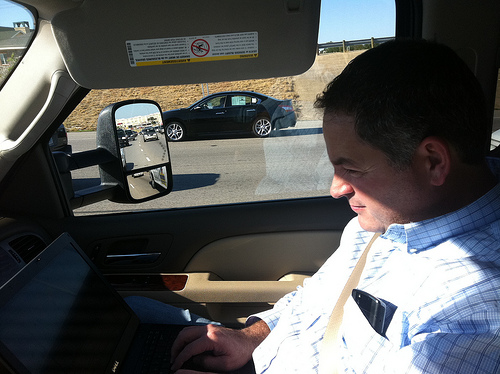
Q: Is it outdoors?
A: Yes, it is outdoors.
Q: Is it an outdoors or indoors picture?
A: It is outdoors.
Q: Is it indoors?
A: No, it is outdoors.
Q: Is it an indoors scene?
A: No, it is outdoors.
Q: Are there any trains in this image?
A: No, there are no trains.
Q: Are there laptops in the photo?
A: Yes, there is a laptop.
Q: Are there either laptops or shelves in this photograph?
A: Yes, there is a laptop.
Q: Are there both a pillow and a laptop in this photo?
A: No, there is a laptop but no pillows.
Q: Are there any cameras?
A: No, there are no cameras.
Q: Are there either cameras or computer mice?
A: No, there are no cameras or computer mice.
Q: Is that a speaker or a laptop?
A: That is a laptop.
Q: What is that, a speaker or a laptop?
A: That is a laptop.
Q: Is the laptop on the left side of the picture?
A: Yes, the laptop is on the left of the image.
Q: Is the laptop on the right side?
A: No, the laptop is on the left of the image.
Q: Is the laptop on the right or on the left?
A: The laptop is on the left of the image.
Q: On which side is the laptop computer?
A: The laptop computer is on the left of the image.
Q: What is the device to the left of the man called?
A: The device is a laptop.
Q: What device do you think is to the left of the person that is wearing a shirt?
A: The device is a laptop.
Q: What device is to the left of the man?
A: The device is a laptop.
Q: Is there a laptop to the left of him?
A: Yes, there is a laptop to the left of the man.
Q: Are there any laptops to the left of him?
A: Yes, there is a laptop to the left of the man.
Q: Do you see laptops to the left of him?
A: Yes, there is a laptop to the left of the man.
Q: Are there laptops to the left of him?
A: Yes, there is a laptop to the left of the man.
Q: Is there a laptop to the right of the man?
A: No, the laptop is to the left of the man.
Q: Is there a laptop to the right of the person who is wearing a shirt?
A: No, the laptop is to the left of the man.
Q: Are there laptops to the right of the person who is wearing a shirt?
A: No, the laptop is to the left of the man.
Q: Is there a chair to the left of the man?
A: No, there is a laptop to the left of the man.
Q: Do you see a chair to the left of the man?
A: No, there is a laptop to the left of the man.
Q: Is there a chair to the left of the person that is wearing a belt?
A: No, there is a laptop to the left of the man.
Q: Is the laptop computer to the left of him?
A: Yes, the laptop computer is to the left of a man.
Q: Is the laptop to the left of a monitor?
A: No, the laptop is to the left of a man.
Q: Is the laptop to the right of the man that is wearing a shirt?
A: No, the laptop is to the left of the man.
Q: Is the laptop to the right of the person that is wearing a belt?
A: No, the laptop is to the left of the man.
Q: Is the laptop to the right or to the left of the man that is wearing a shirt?
A: The laptop is to the left of the man.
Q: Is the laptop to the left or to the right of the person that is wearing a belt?
A: The laptop is to the left of the man.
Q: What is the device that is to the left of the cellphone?
A: The device is a laptop.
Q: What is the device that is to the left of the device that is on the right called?
A: The device is a laptop.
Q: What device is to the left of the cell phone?
A: The device is a laptop.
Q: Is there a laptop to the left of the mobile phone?
A: Yes, there is a laptop to the left of the mobile phone.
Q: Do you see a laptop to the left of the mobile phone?
A: Yes, there is a laptop to the left of the mobile phone.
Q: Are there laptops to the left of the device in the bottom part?
A: Yes, there is a laptop to the left of the mobile phone.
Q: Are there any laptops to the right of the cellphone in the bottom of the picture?
A: No, the laptop is to the left of the cellphone.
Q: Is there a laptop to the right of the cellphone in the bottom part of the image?
A: No, the laptop is to the left of the cellphone.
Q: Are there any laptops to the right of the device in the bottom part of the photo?
A: No, the laptop is to the left of the cellphone.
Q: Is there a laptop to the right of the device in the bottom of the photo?
A: No, the laptop is to the left of the cellphone.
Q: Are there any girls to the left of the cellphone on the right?
A: No, there is a laptop to the left of the cellphone.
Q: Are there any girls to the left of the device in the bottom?
A: No, there is a laptop to the left of the cellphone.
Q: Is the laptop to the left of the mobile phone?
A: Yes, the laptop is to the left of the mobile phone.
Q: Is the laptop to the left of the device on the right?
A: Yes, the laptop is to the left of the mobile phone.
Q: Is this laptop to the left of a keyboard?
A: No, the laptop is to the left of the mobile phone.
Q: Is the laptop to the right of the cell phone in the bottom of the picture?
A: No, the laptop is to the left of the cellphone.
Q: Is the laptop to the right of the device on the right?
A: No, the laptop is to the left of the cellphone.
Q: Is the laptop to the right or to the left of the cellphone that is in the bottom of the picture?
A: The laptop is to the left of the cellphone.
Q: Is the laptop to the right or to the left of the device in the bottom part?
A: The laptop is to the left of the cellphone.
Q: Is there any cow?
A: No, there are no cows.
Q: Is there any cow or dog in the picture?
A: No, there are no cows or dogs.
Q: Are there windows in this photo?
A: Yes, there is a window.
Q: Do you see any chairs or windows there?
A: Yes, there is a window.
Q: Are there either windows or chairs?
A: Yes, there is a window.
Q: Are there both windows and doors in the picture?
A: Yes, there are both a window and a door.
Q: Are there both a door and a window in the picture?
A: Yes, there are both a window and a door.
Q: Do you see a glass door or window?
A: Yes, there is a glass window.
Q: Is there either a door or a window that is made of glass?
A: Yes, the window is made of glass.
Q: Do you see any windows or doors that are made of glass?
A: Yes, the window is made of glass.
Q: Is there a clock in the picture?
A: No, there are no clocks.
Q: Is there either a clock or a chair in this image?
A: No, there are no clocks or chairs.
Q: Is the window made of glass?
A: Yes, the window is made of glass.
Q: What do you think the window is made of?
A: The window is made of glass.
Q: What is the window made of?
A: The window is made of glass.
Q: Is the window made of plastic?
A: No, the window is made of glass.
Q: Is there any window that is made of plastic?
A: No, there is a window but it is made of glass.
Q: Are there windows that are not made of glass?
A: No, there is a window but it is made of glass.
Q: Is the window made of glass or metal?
A: The window is made of glass.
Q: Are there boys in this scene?
A: No, there are no boys.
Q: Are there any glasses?
A: No, there are no glasses.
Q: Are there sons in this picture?
A: No, there are no sons.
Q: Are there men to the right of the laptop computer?
A: Yes, there is a man to the right of the laptop computer.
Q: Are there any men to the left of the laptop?
A: No, the man is to the right of the laptop.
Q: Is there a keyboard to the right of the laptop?
A: No, there is a man to the right of the laptop.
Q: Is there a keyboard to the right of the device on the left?
A: No, there is a man to the right of the laptop.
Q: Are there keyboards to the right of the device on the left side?
A: No, there is a man to the right of the laptop.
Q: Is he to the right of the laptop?
A: Yes, the man is to the right of the laptop.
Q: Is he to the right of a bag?
A: No, the man is to the right of the laptop.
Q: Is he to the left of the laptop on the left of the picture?
A: No, the man is to the right of the laptop.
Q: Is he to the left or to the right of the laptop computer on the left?
A: The man is to the right of the laptop computer.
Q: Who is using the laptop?
A: The man is using the laptop.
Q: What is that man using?
A: The man is using a laptop.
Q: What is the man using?
A: The man is using a laptop.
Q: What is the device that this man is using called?
A: The device is a laptop.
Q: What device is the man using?
A: The man is using a laptop.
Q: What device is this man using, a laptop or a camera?
A: The man is using a laptop.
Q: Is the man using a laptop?
A: Yes, the man is using a laptop.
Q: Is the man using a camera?
A: No, the man is using a laptop.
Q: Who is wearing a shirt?
A: The man is wearing a shirt.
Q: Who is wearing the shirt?
A: The man is wearing a shirt.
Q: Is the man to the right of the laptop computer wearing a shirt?
A: Yes, the man is wearing a shirt.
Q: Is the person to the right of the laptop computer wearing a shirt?
A: Yes, the man is wearing a shirt.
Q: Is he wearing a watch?
A: No, the man is wearing a shirt.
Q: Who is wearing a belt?
A: The man is wearing a belt.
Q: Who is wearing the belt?
A: The man is wearing a belt.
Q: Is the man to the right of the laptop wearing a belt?
A: Yes, the man is wearing a belt.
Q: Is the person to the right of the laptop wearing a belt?
A: Yes, the man is wearing a belt.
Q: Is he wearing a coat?
A: No, the man is wearing a belt.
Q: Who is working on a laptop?
A: The man is working on a laptop.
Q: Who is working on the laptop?
A: The man is working on a laptop.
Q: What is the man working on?
A: The man is working on a laptop.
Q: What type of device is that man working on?
A: The man is working on a laptop.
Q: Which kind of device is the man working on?
A: The man is working on a laptop.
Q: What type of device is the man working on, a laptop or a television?
A: The man is working on a laptop.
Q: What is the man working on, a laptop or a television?
A: The man is working on a laptop.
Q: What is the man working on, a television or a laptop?
A: The man is working on a laptop.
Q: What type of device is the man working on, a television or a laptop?
A: The man is working on a laptop.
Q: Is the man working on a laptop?
A: Yes, the man is working on a laptop.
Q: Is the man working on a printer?
A: No, the man is working on a laptop.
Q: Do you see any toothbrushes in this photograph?
A: No, there are no toothbrushes.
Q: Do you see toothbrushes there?
A: No, there are no toothbrushes.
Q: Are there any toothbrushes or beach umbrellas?
A: No, there are no toothbrushes or beach umbrellas.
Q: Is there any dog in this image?
A: No, there are no dogs.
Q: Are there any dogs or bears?
A: No, there are no dogs or bears.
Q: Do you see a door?
A: Yes, there is a door.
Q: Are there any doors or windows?
A: Yes, there is a door.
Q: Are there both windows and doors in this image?
A: Yes, there are both a door and a window.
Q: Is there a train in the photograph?
A: No, there are no trains.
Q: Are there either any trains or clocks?
A: No, there are no trains or clocks.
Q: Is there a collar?
A: Yes, there is a collar.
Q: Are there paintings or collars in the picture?
A: Yes, there is a collar.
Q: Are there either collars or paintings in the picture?
A: Yes, there is a collar.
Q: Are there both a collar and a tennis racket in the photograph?
A: No, there is a collar but no rackets.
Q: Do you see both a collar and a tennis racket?
A: No, there is a collar but no rackets.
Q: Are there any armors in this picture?
A: No, there are no armors.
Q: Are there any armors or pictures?
A: No, there are no armors or pictures.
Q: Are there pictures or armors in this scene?
A: No, there are no armors or pictures.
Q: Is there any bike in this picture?
A: No, there are no bikes.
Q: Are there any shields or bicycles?
A: No, there are no bicycles or shields.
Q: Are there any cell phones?
A: Yes, there is a cell phone.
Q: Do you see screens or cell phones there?
A: Yes, there is a cell phone.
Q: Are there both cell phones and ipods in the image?
A: No, there is a cell phone but no ipods.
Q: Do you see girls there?
A: No, there are no girls.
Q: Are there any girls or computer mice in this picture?
A: No, there are no girls or computer mice.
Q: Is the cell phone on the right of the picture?
A: Yes, the cell phone is on the right of the image.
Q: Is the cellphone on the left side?
A: No, the cellphone is on the right of the image.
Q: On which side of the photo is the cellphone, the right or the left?
A: The cellphone is on the right of the image.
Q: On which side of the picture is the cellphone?
A: The cellphone is on the right of the image.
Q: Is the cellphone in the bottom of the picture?
A: Yes, the cellphone is in the bottom of the image.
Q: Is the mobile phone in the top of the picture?
A: No, the mobile phone is in the bottom of the image.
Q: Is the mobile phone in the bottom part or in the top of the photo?
A: The mobile phone is in the bottom of the image.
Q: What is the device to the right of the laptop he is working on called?
A: The device is a cell phone.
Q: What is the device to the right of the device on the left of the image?
A: The device is a cell phone.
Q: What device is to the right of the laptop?
A: The device is a cell phone.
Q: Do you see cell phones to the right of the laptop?
A: Yes, there is a cell phone to the right of the laptop.